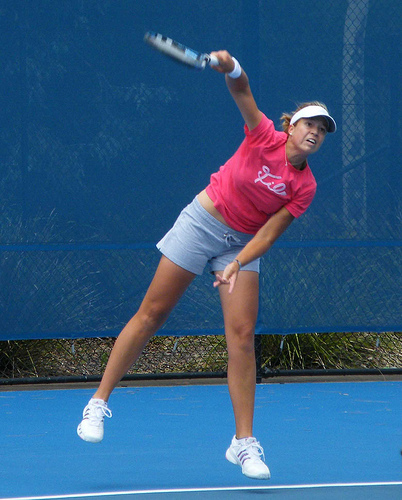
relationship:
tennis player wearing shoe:
[75, 48, 337, 479] [227, 433, 274, 478]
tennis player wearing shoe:
[75, 48, 337, 479] [76, 401, 107, 444]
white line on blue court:
[0, 478, 400, 497] [1, 380, 400, 498]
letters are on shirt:
[252, 162, 287, 194] [206, 115, 318, 230]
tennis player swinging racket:
[75, 48, 337, 479] [141, 23, 219, 71]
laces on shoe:
[242, 438, 264, 459] [76, 395, 113, 446]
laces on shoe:
[82, 399, 113, 416] [225, 436, 274, 480]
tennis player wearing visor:
[75, 48, 337, 479] [290, 105, 337, 133]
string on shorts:
[221, 231, 240, 252] [153, 198, 263, 277]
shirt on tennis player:
[220, 99, 324, 238] [75, 48, 337, 479]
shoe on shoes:
[226, 435, 271, 480] [68, 376, 286, 493]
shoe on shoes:
[76, 397, 113, 443] [68, 376, 286, 493]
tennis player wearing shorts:
[75, 24, 336, 488] [153, 198, 263, 277]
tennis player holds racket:
[75, 24, 336, 488] [136, 29, 214, 70]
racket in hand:
[136, 29, 214, 70] [210, 50, 234, 73]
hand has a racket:
[210, 50, 234, 73] [136, 29, 214, 70]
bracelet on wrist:
[235, 256, 241, 268] [234, 255, 242, 268]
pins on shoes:
[243, 442, 262, 453] [76, 396, 273, 478]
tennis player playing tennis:
[75, 48, 337, 479] [65, 14, 382, 489]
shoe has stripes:
[226, 435, 271, 480] [235, 449, 252, 465]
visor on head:
[290, 105, 337, 133] [288, 101, 329, 155]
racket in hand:
[144, 30, 220, 70] [209, 45, 236, 72]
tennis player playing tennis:
[75, 48, 337, 479] [13, 19, 355, 480]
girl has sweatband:
[70, 24, 357, 496] [226, 54, 243, 78]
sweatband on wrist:
[226, 54, 243, 78] [224, 57, 237, 72]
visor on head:
[275, 101, 343, 132] [291, 107, 337, 153]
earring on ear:
[288, 133, 293, 136] [283, 125, 295, 133]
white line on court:
[0, 478, 400, 497] [0, 46, 400, 500]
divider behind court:
[3, 2, 400, 340] [2, 368, 400, 498]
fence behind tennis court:
[0, 3, 400, 384] [0, 372, 398, 494]